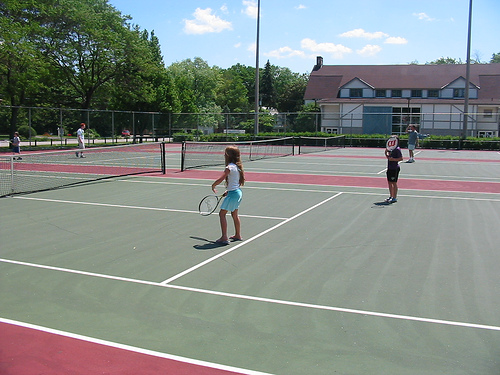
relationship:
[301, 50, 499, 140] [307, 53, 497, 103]
building with roof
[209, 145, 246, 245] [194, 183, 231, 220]
girl with racket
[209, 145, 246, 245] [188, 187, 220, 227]
girl holding racket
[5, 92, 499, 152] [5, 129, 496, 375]
fence around court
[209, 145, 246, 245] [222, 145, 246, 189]
girl with blonde hair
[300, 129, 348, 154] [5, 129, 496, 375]
tennis net on court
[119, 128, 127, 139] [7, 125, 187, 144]
car on street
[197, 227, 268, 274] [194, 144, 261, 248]
shadow of girl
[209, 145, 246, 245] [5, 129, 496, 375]
girl on court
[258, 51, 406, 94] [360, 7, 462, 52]
clouds in sky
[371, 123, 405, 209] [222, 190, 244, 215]
girl wearing shorts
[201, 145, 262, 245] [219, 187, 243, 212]
girl wearing pants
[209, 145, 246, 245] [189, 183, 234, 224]
girl with racket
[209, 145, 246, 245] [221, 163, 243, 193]
girl with shirt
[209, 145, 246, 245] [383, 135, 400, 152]
girl holding racquet